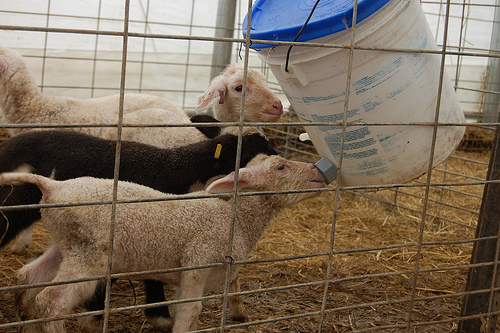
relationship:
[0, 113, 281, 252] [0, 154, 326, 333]
sheep between lambs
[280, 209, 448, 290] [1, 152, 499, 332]
hay on floor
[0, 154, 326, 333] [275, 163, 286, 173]
lambs has eye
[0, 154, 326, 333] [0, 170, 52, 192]
lambs has tail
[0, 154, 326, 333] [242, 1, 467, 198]
lambs drinking from container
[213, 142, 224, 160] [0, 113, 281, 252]
tag on sheep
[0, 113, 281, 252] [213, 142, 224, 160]
sheep has tag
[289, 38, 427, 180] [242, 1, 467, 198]
writing on container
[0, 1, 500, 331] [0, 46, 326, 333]
cage has lambs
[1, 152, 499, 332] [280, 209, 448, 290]
floor has hay